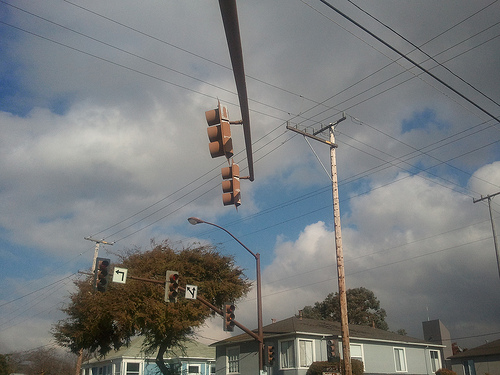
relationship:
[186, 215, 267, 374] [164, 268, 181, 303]
street light above traffic signal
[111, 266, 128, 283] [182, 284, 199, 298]
sign to left of sign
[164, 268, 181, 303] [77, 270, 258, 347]
traffic signal attached to arm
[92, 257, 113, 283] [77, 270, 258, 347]
traffic signal attached to arm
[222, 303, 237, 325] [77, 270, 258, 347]
traffic signal attached to arm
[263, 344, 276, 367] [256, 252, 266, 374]
traffic signal attached to pole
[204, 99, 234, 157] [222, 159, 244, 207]
traffic signal next to traffic signal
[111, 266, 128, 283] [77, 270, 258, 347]
sign attached to arm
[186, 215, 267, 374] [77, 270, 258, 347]
street light above arm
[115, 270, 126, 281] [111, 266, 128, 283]
arrow printed on sign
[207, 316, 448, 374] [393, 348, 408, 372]
house has window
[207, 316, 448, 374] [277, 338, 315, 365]
house has corner window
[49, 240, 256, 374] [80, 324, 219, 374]
tree in front of house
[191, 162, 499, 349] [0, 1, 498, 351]
clouds floating in sky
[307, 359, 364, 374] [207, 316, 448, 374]
bush in front of house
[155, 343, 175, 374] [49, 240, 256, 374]
trunk of tree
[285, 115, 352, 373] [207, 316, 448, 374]
utility pole in front of house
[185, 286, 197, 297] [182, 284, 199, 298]
arrows printed on sign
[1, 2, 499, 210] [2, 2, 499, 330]
wires crossing wires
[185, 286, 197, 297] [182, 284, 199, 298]
arrows visible on sign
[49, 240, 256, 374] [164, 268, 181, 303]
tree behind traffic signal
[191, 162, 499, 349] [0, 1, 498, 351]
clouds located in sky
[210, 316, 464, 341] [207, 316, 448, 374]
roof on top of house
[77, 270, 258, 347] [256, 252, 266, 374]
arm attached to pole